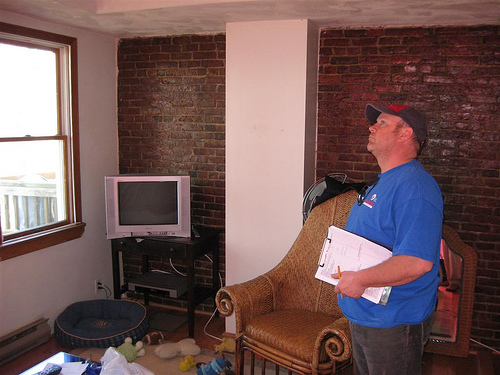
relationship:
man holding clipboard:
[309, 102, 439, 373] [307, 225, 394, 305]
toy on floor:
[115, 337, 145, 362] [1, 300, 303, 374]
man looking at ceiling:
[331, 103, 444, 375] [0, 1, 499, 28]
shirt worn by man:
[337, 154, 442, 328] [331, 103, 444, 375]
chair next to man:
[202, 165, 428, 369] [289, 74, 457, 374]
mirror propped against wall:
[428, 229, 477, 358] [433, 27, 499, 240]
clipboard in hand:
[313, 214, 410, 343] [329, 253, 384, 319]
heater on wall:
[1, 310, 54, 362] [2, 12, 114, 352]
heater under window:
[1, 310, 54, 362] [0, 20, 85, 260]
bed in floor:
[50, 293, 151, 349] [6, 296, 210, 367]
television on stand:
[104, 175, 191, 240] [104, 224, 222, 341]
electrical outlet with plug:
[93, 278, 103, 297] [94, 275, 107, 288]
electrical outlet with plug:
[93, 278, 103, 297] [93, 284, 104, 291]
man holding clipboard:
[331, 103, 444, 375] [307, 225, 394, 305]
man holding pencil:
[331, 103, 444, 375] [335, 263, 344, 300]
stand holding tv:
[111, 225, 222, 338] [99, 164, 187, 216]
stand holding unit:
[111, 225, 222, 338] [125, 262, 197, 302]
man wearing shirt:
[331, 103, 444, 375] [337, 159, 444, 328]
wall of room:
[117, 26, 500, 347] [2, 0, 490, 367]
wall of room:
[319, 20, 497, 335] [2, 0, 490, 367]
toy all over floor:
[112, 335, 150, 366] [81, 282, 308, 372]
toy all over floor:
[149, 327, 203, 358] [81, 282, 308, 372]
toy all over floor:
[212, 327, 241, 354] [81, 282, 308, 372]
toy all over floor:
[173, 349, 213, 373] [81, 282, 308, 372]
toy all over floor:
[194, 351, 232, 372] [81, 282, 308, 372]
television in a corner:
[105, 167, 210, 233] [109, 61, 139, 171]